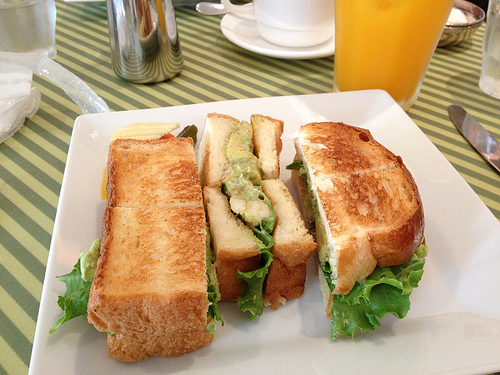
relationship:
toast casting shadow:
[88, 134, 214, 363] [79, 323, 213, 373]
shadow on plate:
[79, 323, 213, 373] [27, 80, 490, 373]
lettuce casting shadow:
[326, 244, 426, 343] [335, 312, 398, 348]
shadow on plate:
[335, 312, 398, 348] [27, 80, 490, 373]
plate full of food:
[58, 88, 479, 364] [105, 120, 386, 314]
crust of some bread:
[127, 300, 196, 361] [103, 128, 201, 348]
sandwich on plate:
[138, 133, 439, 300] [54, 102, 494, 356]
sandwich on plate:
[98, 122, 241, 354] [54, 102, 494, 356]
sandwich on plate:
[210, 111, 322, 312] [54, 102, 494, 356]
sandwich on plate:
[308, 102, 453, 367] [54, 102, 494, 356]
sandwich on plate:
[138, 133, 439, 300] [48, 73, 426, 373]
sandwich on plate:
[138, 133, 439, 300] [50, 86, 490, 333]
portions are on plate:
[93, 115, 424, 365] [27, 80, 490, 373]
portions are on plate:
[80, 98, 440, 358] [27, 80, 490, 373]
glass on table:
[317, 3, 457, 103] [6, 13, 493, 345]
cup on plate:
[247, 5, 336, 50] [210, 6, 333, 66]